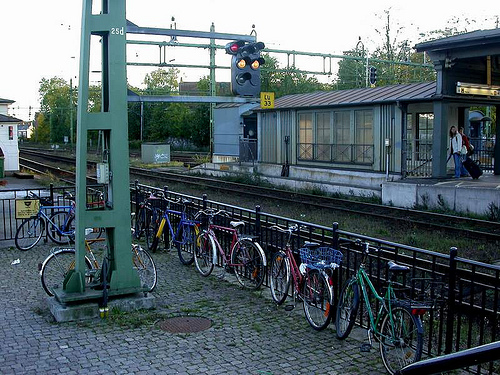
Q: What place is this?
A: It is a train station.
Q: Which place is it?
A: It is a train station.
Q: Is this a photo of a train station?
A: Yes, it is showing a train station.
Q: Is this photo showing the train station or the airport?
A: It is showing the train station.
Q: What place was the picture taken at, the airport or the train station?
A: It was taken at the train station.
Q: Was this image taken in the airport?
A: No, the picture was taken in the train station.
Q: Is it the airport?
A: No, it is the train station.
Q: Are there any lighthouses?
A: No, there are no lighthouses.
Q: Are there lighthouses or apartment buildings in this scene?
A: No, there are no lighthouses or apartment buildings.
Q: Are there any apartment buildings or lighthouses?
A: No, there are no lighthouses or apartment buildings.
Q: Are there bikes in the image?
A: Yes, there is a bike.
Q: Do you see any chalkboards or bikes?
A: Yes, there is a bike.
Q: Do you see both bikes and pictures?
A: No, there is a bike but no pictures.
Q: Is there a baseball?
A: No, there are no baseballs.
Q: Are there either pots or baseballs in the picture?
A: No, there are no baseballs or pots.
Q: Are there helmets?
A: No, there are no helmets.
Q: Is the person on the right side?
A: Yes, the person is on the right of the image.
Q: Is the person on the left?
A: No, the person is on the right of the image.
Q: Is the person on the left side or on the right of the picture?
A: The person is on the right of the image.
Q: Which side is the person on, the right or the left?
A: The person is on the right of the image.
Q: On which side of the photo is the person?
A: The person is on the right of the image.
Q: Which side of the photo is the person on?
A: The person is on the right of the image.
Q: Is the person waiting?
A: Yes, the person is waiting.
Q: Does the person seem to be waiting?
A: Yes, the person is waiting.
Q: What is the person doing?
A: The person is waiting.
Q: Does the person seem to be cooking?
A: No, the person is waiting.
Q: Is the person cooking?
A: No, the person is waiting.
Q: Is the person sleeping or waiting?
A: The person is waiting.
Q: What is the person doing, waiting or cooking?
A: The person is waiting.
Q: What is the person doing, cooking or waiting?
A: The person is waiting.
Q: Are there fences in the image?
A: Yes, there is a fence.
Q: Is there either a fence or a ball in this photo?
A: Yes, there is a fence.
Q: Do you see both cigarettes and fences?
A: No, there is a fence but no cigarettes.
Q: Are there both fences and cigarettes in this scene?
A: No, there is a fence but no cigarettes.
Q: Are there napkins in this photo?
A: No, there are no napkins.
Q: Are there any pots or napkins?
A: No, there are no napkins or pots.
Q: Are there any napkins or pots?
A: No, there are no napkins or pots.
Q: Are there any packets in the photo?
A: No, there are no packets.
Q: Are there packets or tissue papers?
A: No, there are no packets or tissue papers.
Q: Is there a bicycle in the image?
A: Yes, there is a bicycle.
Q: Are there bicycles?
A: Yes, there is a bicycle.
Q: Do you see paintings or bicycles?
A: Yes, there is a bicycle.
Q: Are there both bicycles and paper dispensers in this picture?
A: No, there is a bicycle but no paper dispensers.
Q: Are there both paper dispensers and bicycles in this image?
A: No, there is a bicycle but no paper dispensers.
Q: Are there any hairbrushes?
A: No, there are no hairbrushes.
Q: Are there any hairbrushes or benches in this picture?
A: No, there are no hairbrushes or benches.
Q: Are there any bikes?
A: Yes, there is a bike.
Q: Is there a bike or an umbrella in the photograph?
A: Yes, there is a bike.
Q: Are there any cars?
A: No, there are no cars.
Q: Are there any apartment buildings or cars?
A: No, there are no cars or apartment buildings.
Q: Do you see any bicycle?
A: Yes, there is a bicycle.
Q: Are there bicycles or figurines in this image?
A: Yes, there is a bicycle.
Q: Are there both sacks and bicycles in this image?
A: No, there is a bicycle but no sacks.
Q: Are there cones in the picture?
A: No, there are no cones.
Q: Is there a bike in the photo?
A: Yes, there is a bike.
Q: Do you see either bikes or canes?
A: Yes, there is a bike.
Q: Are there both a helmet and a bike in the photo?
A: No, there is a bike but no helmets.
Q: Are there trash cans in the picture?
A: No, there are no trash cans.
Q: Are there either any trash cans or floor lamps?
A: No, there are no trash cans or floor lamps.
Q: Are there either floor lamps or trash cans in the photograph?
A: No, there are no trash cans or floor lamps.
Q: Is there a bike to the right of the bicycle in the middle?
A: No, the bike is to the left of the bicycle.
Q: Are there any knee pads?
A: No, there are no knee pads.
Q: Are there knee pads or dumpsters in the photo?
A: No, there are no knee pads or dumpsters.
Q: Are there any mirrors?
A: No, there are no mirrors.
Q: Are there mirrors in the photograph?
A: No, there are no mirrors.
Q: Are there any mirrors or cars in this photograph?
A: No, there are no mirrors or cars.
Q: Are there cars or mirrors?
A: No, there are no mirrors or cars.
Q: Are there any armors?
A: No, there are no armors.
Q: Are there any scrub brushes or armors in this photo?
A: No, there are no armors or scrub brushes.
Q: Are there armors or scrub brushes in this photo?
A: No, there are no armors or scrub brushes.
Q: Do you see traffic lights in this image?
A: Yes, there is a traffic light.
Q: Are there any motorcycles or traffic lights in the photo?
A: Yes, there is a traffic light.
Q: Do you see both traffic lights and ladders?
A: No, there is a traffic light but no ladders.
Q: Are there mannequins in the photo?
A: No, there are no mannequins.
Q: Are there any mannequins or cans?
A: No, there are no mannequins or cans.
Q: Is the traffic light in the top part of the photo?
A: Yes, the traffic light is in the top of the image.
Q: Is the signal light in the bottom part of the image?
A: No, the signal light is in the top of the image.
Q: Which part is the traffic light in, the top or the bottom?
A: The traffic light is in the top of the image.